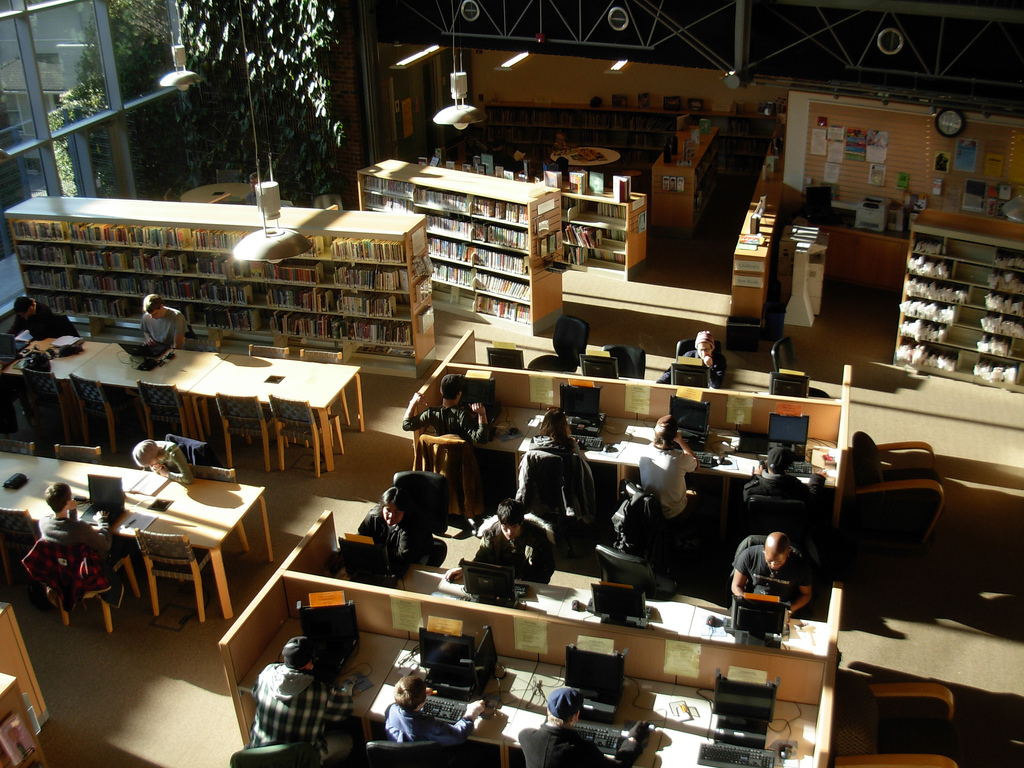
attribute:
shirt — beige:
[644, 442, 675, 495]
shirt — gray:
[156, 315, 172, 337]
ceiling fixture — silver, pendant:
[427, 16, 488, 140]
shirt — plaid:
[248, 660, 344, 753]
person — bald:
[727, 526, 816, 617]